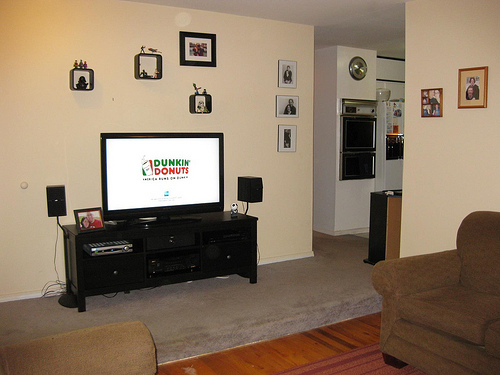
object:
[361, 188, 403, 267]
stand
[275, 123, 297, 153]
frames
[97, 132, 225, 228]
television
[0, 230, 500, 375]
floor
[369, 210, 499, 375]
chairs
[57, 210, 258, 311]
entertainment center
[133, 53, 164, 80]
shelves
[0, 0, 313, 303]
wall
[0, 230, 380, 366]
carpet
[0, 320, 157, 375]
sofa chair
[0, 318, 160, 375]
arm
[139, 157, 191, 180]
advertisement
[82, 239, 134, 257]
box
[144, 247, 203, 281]
shelf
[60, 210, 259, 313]
tv stand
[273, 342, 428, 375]
area rug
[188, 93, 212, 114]
shelves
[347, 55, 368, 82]
clock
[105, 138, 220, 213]
screen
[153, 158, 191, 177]
dunkin' donuts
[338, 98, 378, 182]
oven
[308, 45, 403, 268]
kitchen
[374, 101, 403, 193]
refrigerator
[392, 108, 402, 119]
magnets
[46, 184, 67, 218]
speaker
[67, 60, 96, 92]
bric-a-brack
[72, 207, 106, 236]
photographs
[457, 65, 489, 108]
photographs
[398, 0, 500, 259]
wall